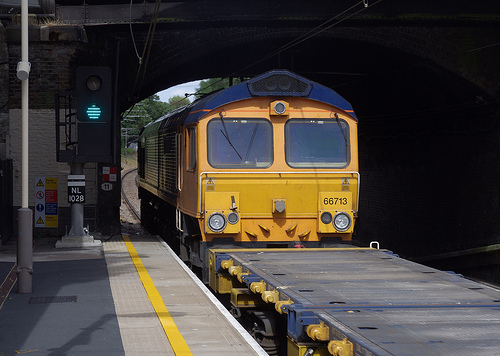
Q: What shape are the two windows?
A: The two windows are square.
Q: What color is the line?
A: The line is yellow.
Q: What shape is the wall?
A: The wall is dome shaped.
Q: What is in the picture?
A: The front of a train engine.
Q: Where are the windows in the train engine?
A: The windows are in the front.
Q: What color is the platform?
A: Gray.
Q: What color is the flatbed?
A: Gray.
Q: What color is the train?
A: Yellow.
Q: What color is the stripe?
A: Yellow.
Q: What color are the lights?
A: Silver.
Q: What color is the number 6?
A: Black.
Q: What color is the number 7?
A: Black.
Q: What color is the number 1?
A: Black.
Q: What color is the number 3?
A: Black.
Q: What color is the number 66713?
A: Black.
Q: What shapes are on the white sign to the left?
A: Triangles and circles.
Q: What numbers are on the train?
A: 66713.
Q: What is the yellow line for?
A: Keep passengers back.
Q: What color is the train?
A: Yellow.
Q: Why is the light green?
A: To go.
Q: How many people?
A: 0.